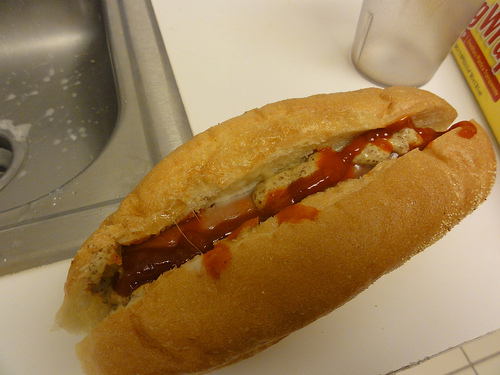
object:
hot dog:
[58, 84, 499, 373]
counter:
[2, 2, 499, 374]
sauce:
[129, 116, 429, 278]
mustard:
[186, 150, 385, 199]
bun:
[85, 79, 499, 375]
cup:
[350, 0, 484, 89]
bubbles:
[1, 52, 99, 99]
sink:
[0, 2, 182, 279]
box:
[451, 2, 500, 143]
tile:
[389, 342, 499, 374]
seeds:
[410, 168, 493, 252]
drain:
[0, 122, 29, 187]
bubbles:
[65, 118, 83, 143]